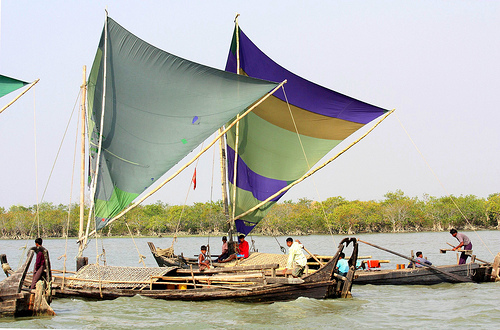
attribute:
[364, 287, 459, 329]
river — scene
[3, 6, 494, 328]
outside — scene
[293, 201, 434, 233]
trees — background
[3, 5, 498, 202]
sky — grey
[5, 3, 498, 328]
sunny day — bright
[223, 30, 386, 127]
trim — purple